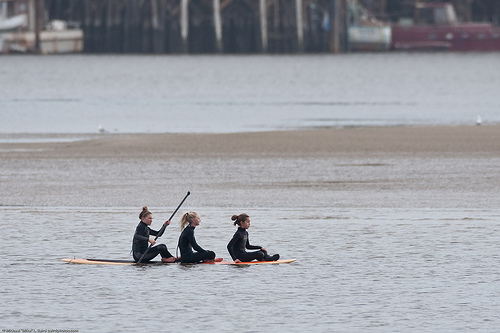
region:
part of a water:
[338, 257, 373, 309]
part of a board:
[277, 240, 310, 260]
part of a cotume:
[228, 232, 253, 267]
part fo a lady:
[165, 187, 201, 266]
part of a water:
[371, 227, 428, 298]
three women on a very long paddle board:
[43, 172, 317, 300]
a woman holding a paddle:
[125, 177, 196, 297]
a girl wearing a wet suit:
[221, 200, 291, 276]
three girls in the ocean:
[59, 200, 307, 309]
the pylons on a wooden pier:
[9, 0, 369, 69]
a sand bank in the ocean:
[80, 86, 480, 175]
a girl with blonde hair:
[167, 206, 222, 273]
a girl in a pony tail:
[228, 203, 283, 288]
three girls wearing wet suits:
[121, 189, 291, 284]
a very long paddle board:
[45, 247, 312, 282]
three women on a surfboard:
[63, 189, 294, 266]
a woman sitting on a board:
[133, 207, 174, 264]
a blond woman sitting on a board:
[177, 212, 216, 264]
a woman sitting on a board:
[226, 211, 278, 266]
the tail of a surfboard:
[62, 254, 130, 265]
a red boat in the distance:
[388, 20, 498, 48]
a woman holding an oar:
[131, 191, 189, 271]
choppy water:
[3, 268, 498, 331]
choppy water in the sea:
[8, 56, 498, 186]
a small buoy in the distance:
[473, 113, 483, 127]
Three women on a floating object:
[60, 191, 308, 280]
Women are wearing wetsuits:
[120, 188, 282, 275]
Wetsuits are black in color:
[111, 202, 283, 273]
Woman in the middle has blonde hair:
[171, 203, 213, 229]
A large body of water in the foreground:
[4, 56, 499, 331]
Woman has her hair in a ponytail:
[171, 204, 210, 233]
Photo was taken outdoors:
[4, 6, 499, 326]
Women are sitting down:
[111, 195, 290, 281]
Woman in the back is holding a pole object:
[114, 187, 193, 277]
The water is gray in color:
[6, 57, 492, 331]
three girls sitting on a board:
[77, 170, 311, 292]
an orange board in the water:
[75, 229, 315, 294]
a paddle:
[130, 180, 197, 279]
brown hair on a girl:
[217, 207, 259, 244]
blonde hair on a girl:
[172, 195, 214, 244]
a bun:
[126, 192, 174, 236]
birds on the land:
[462, 112, 491, 127]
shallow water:
[245, 212, 379, 331]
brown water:
[346, 283, 459, 330]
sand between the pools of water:
[204, 107, 431, 187]